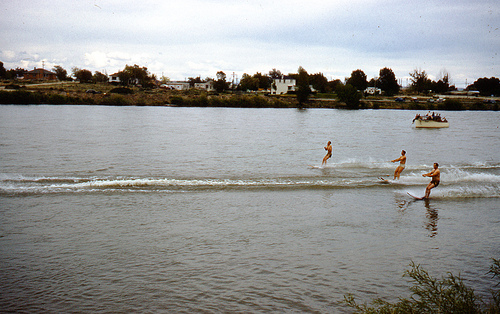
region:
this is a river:
[41, 50, 416, 270]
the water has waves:
[130, 125, 275, 232]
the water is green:
[65, 120, 195, 200]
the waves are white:
[130, 155, 303, 232]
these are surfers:
[270, 150, 497, 220]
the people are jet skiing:
[287, 105, 457, 252]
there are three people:
[303, 123, 464, 253]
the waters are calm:
[116, 175, 326, 311]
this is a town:
[100, 55, 230, 105]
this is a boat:
[382, 93, 494, 167]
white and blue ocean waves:
[57, 135, 87, 156]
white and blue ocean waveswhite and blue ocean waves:
[205, 142, 236, 166]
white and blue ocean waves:
[247, 236, 299, 270]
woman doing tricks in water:
[316, 122, 334, 174]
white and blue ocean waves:
[126, 176, 153, 211]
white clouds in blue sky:
[195, 18, 240, 40]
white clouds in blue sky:
[383, 21, 431, 42]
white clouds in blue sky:
[160, 18, 215, 45]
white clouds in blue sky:
[56, 29, 114, 57]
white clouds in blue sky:
[259, 21, 300, 41]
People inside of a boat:
[411, 109, 453, 131]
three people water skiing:
[321, 135, 444, 209]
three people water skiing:
[315, 133, 448, 223]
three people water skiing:
[313, 137, 443, 206]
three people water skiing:
[319, 140, 443, 204]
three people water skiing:
[313, 135, 450, 208]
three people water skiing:
[308, 134, 437, 224]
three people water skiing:
[313, 133, 454, 205]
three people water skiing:
[309, 123, 454, 218]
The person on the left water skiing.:
[321, 138, 335, 165]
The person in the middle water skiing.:
[386, 146, 409, 185]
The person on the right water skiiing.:
[422, 158, 442, 205]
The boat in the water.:
[409, 112, 449, 128]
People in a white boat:
[410, 106, 452, 143]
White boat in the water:
[398, 104, 455, 137]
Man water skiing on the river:
[399, 155, 450, 205]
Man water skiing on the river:
[389, 148, 411, 182]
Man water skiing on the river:
[313, 135, 345, 172]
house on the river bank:
[266, 68, 304, 99]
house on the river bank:
[363, 81, 380, 95]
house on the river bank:
[191, 75, 218, 91]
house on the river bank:
[157, 78, 189, 93]